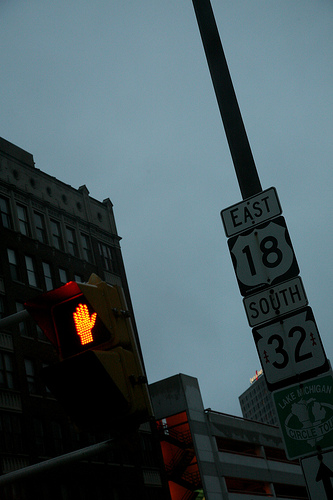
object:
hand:
[72, 304, 99, 346]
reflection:
[49, 280, 83, 310]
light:
[153, 409, 202, 499]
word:
[299, 383, 333, 399]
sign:
[270, 372, 332, 458]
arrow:
[262, 347, 274, 370]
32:
[270, 324, 310, 371]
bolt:
[275, 307, 283, 315]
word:
[249, 285, 300, 321]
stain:
[254, 230, 259, 237]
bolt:
[255, 230, 258, 235]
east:
[231, 194, 273, 226]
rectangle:
[222, 185, 283, 236]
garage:
[149, 374, 326, 500]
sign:
[55, 287, 110, 359]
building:
[0, 132, 300, 499]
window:
[6, 245, 21, 285]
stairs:
[155, 429, 194, 452]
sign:
[220, 186, 282, 238]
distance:
[0, 0, 327, 428]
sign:
[246, 365, 264, 389]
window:
[77, 228, 93, 267]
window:
[15, 199, 32, 241]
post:
[193, 0, 264, 203]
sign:
[298, 450, 333, 498]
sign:
[251, 304, 331, 392]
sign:
[242, 276, 309, 328]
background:
[0, 135, 332, 495]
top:
[0, 135, 37, 177]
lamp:
[190, 0, 214, 6]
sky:
[0, 2, 331, 420]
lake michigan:
[280, 383, 332, 406]